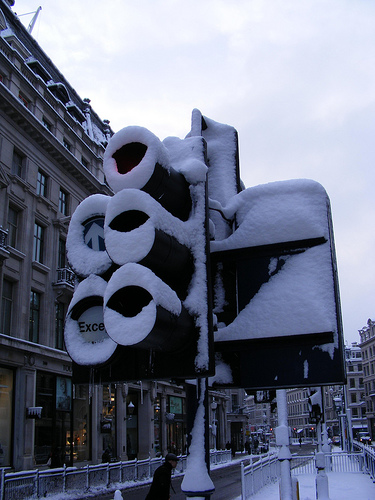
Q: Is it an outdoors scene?
A: Yes, it is outdoors.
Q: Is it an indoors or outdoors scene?
A: It is outdoors.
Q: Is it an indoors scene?
A: No, it is outdoors.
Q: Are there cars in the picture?
A: No, there are no cars.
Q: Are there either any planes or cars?
A: No, there are no cars or planes.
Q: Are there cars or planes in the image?
A: No, there are no cars or planes.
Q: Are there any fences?
A: Yes, there is a fence.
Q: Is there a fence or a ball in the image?
A: Yes, there is a fence.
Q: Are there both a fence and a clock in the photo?
A: No, there is a fence but no clocks.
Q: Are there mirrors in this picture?
A: No, there are no mirrors.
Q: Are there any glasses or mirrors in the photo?
A: No, there are no mirrors or glasses.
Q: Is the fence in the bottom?
A: Yes, the fence is in the bottom of the image.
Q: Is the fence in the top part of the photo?
A: No, the fence is in the bottom of the image.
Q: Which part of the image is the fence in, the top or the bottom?
A: The fence is in the bottom of the image.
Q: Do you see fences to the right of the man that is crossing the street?
A: Yes, there is a fence to the right of the man.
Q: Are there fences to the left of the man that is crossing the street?
A: No, the fence is to the right of the man.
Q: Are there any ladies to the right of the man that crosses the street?
A: No, there is a fence to the right of the man.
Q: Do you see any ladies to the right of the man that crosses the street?
A: No, there is a fence to the right of the man.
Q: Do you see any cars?
A: No, there are no cars.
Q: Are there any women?
A: No, there are no women.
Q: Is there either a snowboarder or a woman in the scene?
A: No, there are no women or snowboarders.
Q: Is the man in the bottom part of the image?
A: Yes, the man is in the bottom of the image.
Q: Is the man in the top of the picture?
A: No, the man is in the bottom of the image.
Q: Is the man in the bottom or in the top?
A: The man is in the bottom of the image.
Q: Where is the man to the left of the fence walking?
A: The man is walking on the street.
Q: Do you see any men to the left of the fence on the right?
A: Yes, there is a man to the left of the fence.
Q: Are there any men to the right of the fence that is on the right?
A: No, the man is to the left of the fence.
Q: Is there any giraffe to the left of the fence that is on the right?
A: No, there is a man to the left of the fence.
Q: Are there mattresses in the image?
A: No, there are no mattresses.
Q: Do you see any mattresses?
A: No, there are no mattresses.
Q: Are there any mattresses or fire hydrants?
A: No, there are no mattresses or fire hydrants.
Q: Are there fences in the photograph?
A: Yes, there is a fence.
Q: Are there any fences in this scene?
A: Yes, there is a fence.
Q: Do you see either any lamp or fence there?
A: Yes, there is a fence.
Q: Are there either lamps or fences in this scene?
A: Yes, there is a fence.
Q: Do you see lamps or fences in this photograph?
A: Yes, there is a fence.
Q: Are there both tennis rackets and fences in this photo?
A: No, there is a fence but no rackets.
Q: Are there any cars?
A: No, there are no cars.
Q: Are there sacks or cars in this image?
A: No, there are no cars or sacks.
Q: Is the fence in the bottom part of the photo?
A: Yes, the fence is in the bottom of the image.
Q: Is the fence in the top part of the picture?
A: No, the fence is in the bottom of the image.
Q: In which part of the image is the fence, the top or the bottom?
A: The fence is in the bottom of the image.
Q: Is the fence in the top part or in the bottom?
A: The fence is in the bottom of the image.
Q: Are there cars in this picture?
A: No, there are no cars.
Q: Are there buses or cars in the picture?
A: No, there are no cars or buses.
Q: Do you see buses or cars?
A: No, there are no cars or buses.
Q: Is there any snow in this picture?
A: Yes, there is snow.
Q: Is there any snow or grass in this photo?
A: Yes, there is snow.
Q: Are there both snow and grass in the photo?
A: No, there is snow but no grass.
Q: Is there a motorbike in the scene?
A: No, there are no motorcycles.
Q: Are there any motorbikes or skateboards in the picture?
A: No, there are no motorbikes or skateboards.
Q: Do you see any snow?
A: Yes, there is snow.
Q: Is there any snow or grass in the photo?
A: Yes, there is snow.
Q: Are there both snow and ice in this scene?
A: No, there is snow but no ice.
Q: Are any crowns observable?
A: No, there are no crowns.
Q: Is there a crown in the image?
A: No, there are no crowns.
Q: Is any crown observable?
A: No, there are no crowns.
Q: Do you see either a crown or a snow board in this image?
A: No, there are no crowns or snowboards.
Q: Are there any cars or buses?
A: No, there are no cars or buses.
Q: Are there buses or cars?
A: No, there are no cars or buses.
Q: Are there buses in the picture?
A: No, there are no buses.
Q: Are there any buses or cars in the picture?
A: No, there are no buses or cars.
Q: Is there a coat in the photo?
A: Yes, there is a coat.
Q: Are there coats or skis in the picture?
A: Yes, there is a coat.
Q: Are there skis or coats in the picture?
A: Yes, there is a coat.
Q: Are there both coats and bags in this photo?
A: No, there is a coat but no bags.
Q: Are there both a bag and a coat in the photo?
A: No, there is a coat but no bags.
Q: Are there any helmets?
A: No, there are no helmets.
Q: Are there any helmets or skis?
A: No, there are no helmets or skis.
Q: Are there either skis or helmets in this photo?
A: No, there are no helmets or skis.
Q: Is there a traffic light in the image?
A: Yes, there is a traffic light.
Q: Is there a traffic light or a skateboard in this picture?
A: Yes, there is a traffic light.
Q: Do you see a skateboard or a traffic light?
A: Yes, there is a traffic light.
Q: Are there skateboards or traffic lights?
A: Yes, there is a traffic light.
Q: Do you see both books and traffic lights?
A: No, there is a traffic light but no books.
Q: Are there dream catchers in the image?
A: No, there are no dream catchers.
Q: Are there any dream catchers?
A: No, there are no dream catchers.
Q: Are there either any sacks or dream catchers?
A: No, there are no dream catchers or sacks.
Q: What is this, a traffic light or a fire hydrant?
A: This is a traffic light.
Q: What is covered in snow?
A: The signal light is covered in snow.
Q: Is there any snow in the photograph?
A: Yes, there is snow.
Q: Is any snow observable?
A: Yes, there is snow.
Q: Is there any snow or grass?
A: Yes, there is snow.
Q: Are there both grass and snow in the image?
A: No, there is snow but no grass.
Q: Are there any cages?
A: No, there are no cages.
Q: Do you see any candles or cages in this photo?
A: No, there are no cages or candles.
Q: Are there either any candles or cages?
A: No, there are no cages or candles.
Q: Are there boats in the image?
A: No, there are no boats.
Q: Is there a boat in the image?
A: No, there are no boats.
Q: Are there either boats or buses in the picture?
A: No, there are no boats or buses.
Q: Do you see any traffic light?
A: Yes, there is a traffic light.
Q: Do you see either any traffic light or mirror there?
A: Yes, there is a traffic light.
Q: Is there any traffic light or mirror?
A: Yes, there is a traffic light.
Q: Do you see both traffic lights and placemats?
A: No, there is a traffic light but no placemats.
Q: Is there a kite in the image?
A: No, there are no kites.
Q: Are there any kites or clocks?
A: No, there are no kites or clocks.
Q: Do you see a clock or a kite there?
A: No, there are no kites or clocks.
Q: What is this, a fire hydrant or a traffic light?
A: This is a traffic light.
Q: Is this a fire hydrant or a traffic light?
A: This is a traffic light.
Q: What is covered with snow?
A: The traffic signal is covered with snow.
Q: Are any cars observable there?
A: No, there are no cars.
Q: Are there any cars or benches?
A: No, there are no cars or benches.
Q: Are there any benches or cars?
A: No, there are no cars or benches.